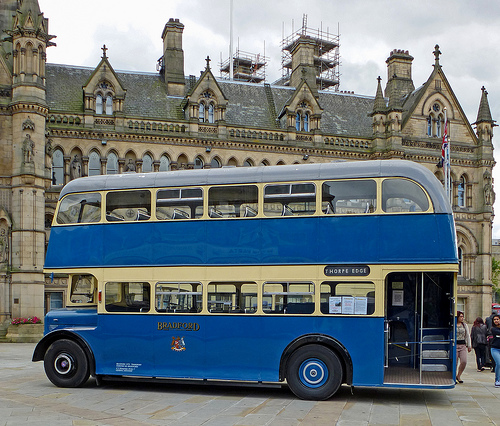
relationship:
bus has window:
[26, 155, 468, 402] [317, 281, 377, 318]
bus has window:
[26, 155, 468, 402] [318, 178, 378, 217]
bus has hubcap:
[26, 155, 468, 402] [297, 357, 329, 389]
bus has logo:
[26, 155, 468, 402] [167, 335, 187, 353]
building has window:
[1, 0, 496, 349] [92, 91, 115, 118]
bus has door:
[26, 155, 468, 402] [385, 272, 457, 388]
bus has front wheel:
[26, 155, 468, 402] [44, 336, 91, 390]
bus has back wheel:
[26, 155, 468, 402] [282, 343, 342, 401]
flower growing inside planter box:
[9, 312, 44, 328] [2, 322, 48, 343]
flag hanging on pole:
[435, 119, 451, 178] [440, 106, 452, 206]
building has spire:
[1, 0, 496, 349] [0, 0, 58, 320]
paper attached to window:
[327, 294, 368, 319] [317, 281, 377, 318]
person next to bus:
[449, 310, 473, 385] [26, 155, 468, 402]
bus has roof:
[26, 155, 468, 402] [56, 156, 454, 213]